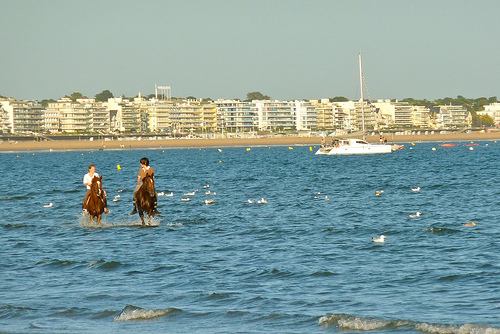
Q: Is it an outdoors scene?
A: Yes, it is outdoors.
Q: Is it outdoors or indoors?
A: It is outdoors.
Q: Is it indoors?
A: No, it is outdoors.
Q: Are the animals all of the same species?
A: No, there are both horses and birds.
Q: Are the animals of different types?
A: Yes, they are horses and birds.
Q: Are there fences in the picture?
A: No, there are no fences.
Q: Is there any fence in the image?
A: No, there are no fences.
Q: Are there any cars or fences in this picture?
A: No, there are no fences or cars.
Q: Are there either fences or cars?
A: No, there are no fences or cars.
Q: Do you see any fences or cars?
A: No, there are no fences or cars.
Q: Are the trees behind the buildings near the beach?
A: Yes, the trees are behind the buildings.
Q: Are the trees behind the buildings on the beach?
A: Yes, the trees are behind the buildings.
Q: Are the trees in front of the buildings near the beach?
A: No, the trees are behind the buildings.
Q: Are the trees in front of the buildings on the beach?
A: No, the trees are behind the buildings.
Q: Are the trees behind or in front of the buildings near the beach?
A: The trees are behind the buildings.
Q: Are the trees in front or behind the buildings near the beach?
A: The trees are behind the buildings.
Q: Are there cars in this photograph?
A: No, there are no cars.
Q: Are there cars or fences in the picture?
A: No, there are no cars or fences.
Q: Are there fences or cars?
A: No, there are no cars or fences.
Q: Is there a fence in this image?
A: No, there are no fences.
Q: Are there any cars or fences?
A: No, there are no fences or cars.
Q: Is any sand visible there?
A: Yes, there is sand.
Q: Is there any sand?
A: Yes, there is sand.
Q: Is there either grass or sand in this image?
A: Yes, there is sand.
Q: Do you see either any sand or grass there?
A: Yes, there is sand.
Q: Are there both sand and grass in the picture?
A: No, there is sand but no grass.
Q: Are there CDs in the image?
A: No, there are no cds.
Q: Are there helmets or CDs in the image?
A: No, there are no CDs or helmets.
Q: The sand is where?
A: The sand is on the shore.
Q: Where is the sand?
A: The sand is on the shore.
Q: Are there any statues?
A: No, there are no statues.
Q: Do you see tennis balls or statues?
A: No, there are no statues or tennis balls.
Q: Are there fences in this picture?
A: No, there are no fences.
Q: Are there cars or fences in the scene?
A: No, there are no fences or cars.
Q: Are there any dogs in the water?
A: No, there is a person in the water.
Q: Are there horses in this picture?
A: Yes, there is a horse.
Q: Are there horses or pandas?
A: Yes, there is a horse.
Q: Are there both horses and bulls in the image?
A: No, there is a horse but no bulls.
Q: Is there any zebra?
A: No, there are no zebras.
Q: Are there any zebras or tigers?
A: No, there are no zebras or tigers.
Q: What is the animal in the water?
A: The animal is a horse.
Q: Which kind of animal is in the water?
A: The animal is a horse.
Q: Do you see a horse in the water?
A: Yes, there is a horse in the water.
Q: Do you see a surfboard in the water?
A: No, there is a horse in the water.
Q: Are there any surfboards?
A: No, there are no surfboards.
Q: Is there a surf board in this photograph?
A: No, there are no surfboards.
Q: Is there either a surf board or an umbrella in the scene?
A: No, there are no surfboards or umbrellas.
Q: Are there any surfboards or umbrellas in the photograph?
A: No, there are no surfboards or umbrellas.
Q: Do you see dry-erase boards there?
A: No, there are no dry-erase boards.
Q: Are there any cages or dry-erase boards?
A: No, there are no dry-erase boards or cages.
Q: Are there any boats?
A: Yes, there is a boat.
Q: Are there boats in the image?
A: Yes, there is a boat.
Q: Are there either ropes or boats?
A: Yes, there is a boat.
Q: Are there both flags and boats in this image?
A: No, there is a boat but no flags.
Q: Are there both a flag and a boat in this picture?
A: No, there is a boat but no flags.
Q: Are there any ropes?
A: No, there are no ropes.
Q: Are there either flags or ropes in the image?
A: No, there are no ropes or flags.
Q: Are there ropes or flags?
A: No, there are no ropes or flags.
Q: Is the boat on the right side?
A: Yes, the boat is on the right of the image.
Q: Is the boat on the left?
A: No, the boat is on the right of the image.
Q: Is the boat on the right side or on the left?
A: The boat is on the right of the image.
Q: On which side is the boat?
A: The boat is on the right of the image.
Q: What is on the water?
A: The boat is on the water.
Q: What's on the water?
A: The boat is on the water.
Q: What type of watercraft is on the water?
A: The watercraft is a boat.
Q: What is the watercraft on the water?
A: The watercraft is a boat.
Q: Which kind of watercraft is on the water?
A: The watercraft is a boat.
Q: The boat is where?
A: The boat is on the water.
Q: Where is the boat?
A: The boat is on the water.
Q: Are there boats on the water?
A: Yes, there is a boat on the water.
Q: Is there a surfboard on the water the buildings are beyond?
A: No, there is a boat on the water.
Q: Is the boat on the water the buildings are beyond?
A: Yes, the boat is on the water.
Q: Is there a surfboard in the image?
A: No, there are no surfboards.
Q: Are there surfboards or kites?
A: No, there are no surfboards or kites.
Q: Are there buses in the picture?
A: No, there are no buses.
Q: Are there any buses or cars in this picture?
A: No, there are no buses or cars.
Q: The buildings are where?
A: The buildings are on the beach.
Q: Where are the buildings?
A: The buildings are on the beach.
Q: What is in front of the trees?
A: The buildings are in front of the trees.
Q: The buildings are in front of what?
A: The buildings are in front of the trees.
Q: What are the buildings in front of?
A: The buildings are in front of the trees.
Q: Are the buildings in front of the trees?
A: Yes, the buildings are in front of the trees.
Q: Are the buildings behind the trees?
A: No, the buildings are in front of the trees.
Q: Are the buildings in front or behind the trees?
A: The buildings are in front of the trees.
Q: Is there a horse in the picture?
A: Yes, there is a horse.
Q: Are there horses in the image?
A: Yes, there is a horse.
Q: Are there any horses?
A: Yes, there is a horse.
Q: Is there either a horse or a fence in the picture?
A: Yes, there is a horse.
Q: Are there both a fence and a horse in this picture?
A: No, there is a horse but no fences.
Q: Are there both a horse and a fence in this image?
A: No, there is a horse but no fences.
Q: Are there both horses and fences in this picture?
A: No, there is a horse but no fences.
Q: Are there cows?
A: No, there are no cows.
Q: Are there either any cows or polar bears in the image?
A: No, there are no cows or polar bears.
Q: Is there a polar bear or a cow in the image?
A: No, there are no cows or polar bears.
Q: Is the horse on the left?
A: Yes, the horse is on the left of the image.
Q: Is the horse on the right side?
A: No, the horse is on the left of the image.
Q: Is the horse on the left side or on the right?
A: The horse is on the left of the image.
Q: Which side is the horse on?
A: The horse is on the left of the image.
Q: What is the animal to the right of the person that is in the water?
A: The animal is a horse.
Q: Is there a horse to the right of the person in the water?
A: Yes, there is a horse to the right of the person.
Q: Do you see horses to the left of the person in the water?
A: No, the horse is to the right of the person.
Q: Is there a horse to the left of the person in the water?
A: No, the horse is to the right of the person.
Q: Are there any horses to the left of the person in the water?
A: No, the horse is to the right of the person.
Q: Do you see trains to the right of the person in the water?
A: No, there is a horse to the right of the person.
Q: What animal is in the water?
A: The animal is a horse.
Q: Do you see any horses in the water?
A: Yes, there is a horse in the water.